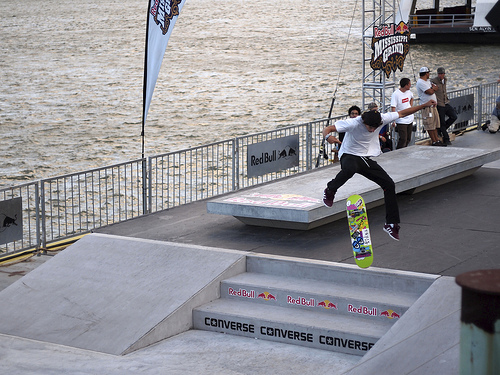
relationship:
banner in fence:
[245, 133, 300, 180] [0, 78, 499, 260]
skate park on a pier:
[22, 192, 496, 372] [254, 122, 498, 277]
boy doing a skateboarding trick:
[322, 99, 439, 242] [319, 153, 402, 271]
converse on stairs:
[205, 317, 256, 334] [189, 254, 435, 357]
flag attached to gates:
[143, 0, 170, 121] [2, 143, 279, 255]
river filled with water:
[0, 0, 497, 259] [22, 0, 124, 160]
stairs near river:
[189, 254, 435, 357] [1, 3, 264, 132]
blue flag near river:
[138, 2, 183, 115] [194, 26, 293, 96]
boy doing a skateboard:
[276, 64, 493, 293] [345, 194, 372, 268]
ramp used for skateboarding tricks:
[3, 225, 268, 353] [321, 102, 441, 272]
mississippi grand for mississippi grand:
[369, 21, 411, 79] [372, 27, 417, 67]